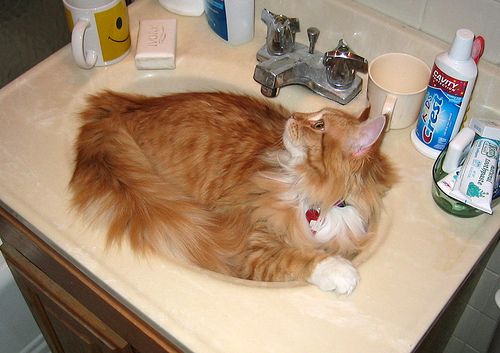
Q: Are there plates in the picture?
A: No, there are no plates.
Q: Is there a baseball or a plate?
A: No, there are no plates or baseballs.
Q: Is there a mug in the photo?
A: Yes, there is a mug.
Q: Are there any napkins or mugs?
A: Yes, there is a mug.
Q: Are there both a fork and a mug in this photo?
A: No, there is a mug but no forks.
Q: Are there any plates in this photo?
A: No, there are no plates.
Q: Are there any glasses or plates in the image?
A: No, there are no plates or glasses.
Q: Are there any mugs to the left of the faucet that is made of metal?
A: Yes, there is a mug to the left of the faucet.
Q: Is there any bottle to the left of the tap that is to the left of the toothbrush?
A: No, there is a mug to the left of the tap.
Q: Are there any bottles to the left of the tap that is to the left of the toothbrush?
A: No, there is a mug to the left of the tap.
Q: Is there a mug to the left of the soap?
A: Yes, there is a mug to the left of the soap.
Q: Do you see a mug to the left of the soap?
A: Yes, there is a mug to the left of the soap.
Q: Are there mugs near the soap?
A: Yes, there is a mug near the soap.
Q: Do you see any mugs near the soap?
A: Yes, there is a mug near the soap.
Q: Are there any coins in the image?
A: No, there are no coins.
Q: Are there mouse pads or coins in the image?
A: No, there are no coins or mouse pads.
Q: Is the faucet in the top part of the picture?
A: Yes, the faucet is in the top of the image.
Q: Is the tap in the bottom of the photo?
A: No, the tap is in the top of the image.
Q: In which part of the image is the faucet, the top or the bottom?
A: The faucet is in the top of the image.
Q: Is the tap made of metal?
A: Yes, the tap is made of metal.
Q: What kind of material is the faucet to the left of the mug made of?
A: The faucet is made of metal.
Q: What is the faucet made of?
A: The faucet is made of metal.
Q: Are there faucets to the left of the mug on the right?
A: Yes, there is a faucet to the left of the mug.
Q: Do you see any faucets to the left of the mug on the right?
A: Yes, there is a faucet to the left of the mug.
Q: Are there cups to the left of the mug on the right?
A: No, there is a faucet to the left of the mug.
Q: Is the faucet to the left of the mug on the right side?
A: Yes, the faucet is to the left of the mug.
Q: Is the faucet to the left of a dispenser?
A: No, the faucet is to the left of the mug.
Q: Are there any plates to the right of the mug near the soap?
A: No, there is a faucet to the right of the mug.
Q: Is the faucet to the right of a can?
A: No, the faucet is to the right of the mug.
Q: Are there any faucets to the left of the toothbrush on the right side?
A: Yes, there is a faucet to the left of the toothbrush.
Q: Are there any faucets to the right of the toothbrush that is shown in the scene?
A: No, the faucet is to the left of the toothbrush.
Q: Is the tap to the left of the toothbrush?
A: Yes, the tap is to the left of the toothbrush.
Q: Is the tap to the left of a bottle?
A: No, the tap is to the left of the toothbrush.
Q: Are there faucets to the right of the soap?
A: Yes, there is a faucet to the right of the soap.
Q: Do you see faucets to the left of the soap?
A: No, the faucet is to the right of the soap.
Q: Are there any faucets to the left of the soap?
A: No, the faucet is to the right of the soap.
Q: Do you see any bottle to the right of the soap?
A: No, there is a faucet to the right of the soap.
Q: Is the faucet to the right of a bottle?
A: No, the faucet is to the right of the soap.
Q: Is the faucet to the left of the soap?
A: No, the faucet is to the right of the soap.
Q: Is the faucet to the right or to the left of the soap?
A: The faucet is to the right of the soap.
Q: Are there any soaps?
A: Yes, there is a soap.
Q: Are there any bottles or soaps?
A: Yes, there is a soap.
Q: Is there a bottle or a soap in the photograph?
A: Yes, there is a soap.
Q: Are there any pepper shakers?
A: No, there are no pepper shakers.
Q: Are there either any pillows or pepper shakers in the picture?
A: No, there are no pepper shakers or pillows.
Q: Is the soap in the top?
A: Yes, the soap is in the top of the image.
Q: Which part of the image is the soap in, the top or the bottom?
A: The soap is in the top of the image.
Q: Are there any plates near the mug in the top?
A: No, there is a soap near the mug.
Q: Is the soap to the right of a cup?
A: No, the soap is to the right of the mug.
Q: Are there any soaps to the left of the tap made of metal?
A: Yes, there is a soap to the left of the faucet.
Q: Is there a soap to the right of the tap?
A: No, the soap is to the left of the tap.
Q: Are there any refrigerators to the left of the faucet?
A: No, there is a soap to the left of the faucet.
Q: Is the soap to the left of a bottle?
A: No, the soap is to the left of a faucet.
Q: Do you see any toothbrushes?
A: Yes, there is a toothbrush.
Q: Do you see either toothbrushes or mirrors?
A: Yes, there is a toothbrush.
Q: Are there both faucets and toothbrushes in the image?
A: Yes, there are both a toothbrush and a faucet.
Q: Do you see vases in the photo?
A: No, there are no vases.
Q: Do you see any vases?
A: No, there are no vases.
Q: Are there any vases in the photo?
A: No, there are no vases.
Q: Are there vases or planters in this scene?
A: No, there are no vases or planters.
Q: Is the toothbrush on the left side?
A: No, the toothbrush is on the right of the image.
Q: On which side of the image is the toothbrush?
A: The toothbrush is on the right of the image.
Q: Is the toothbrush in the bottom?
A: No, the toothbrush is in the top of the image.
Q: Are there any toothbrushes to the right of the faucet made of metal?
A: Yes, there is a toothbrush to the right of the faucet.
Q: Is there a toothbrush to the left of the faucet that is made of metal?
A: No, the toothbrush is to the right of the tap.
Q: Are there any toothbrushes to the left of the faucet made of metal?
A: No, the toothbrush is to the right of the tap.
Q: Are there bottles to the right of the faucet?
A: No, there is a toothbrush to the right of the faucet.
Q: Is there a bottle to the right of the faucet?
A: No, there is a toothbrush to the right of the faucet.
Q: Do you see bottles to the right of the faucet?
A: No, there is a toothbrush to the right of the faucet.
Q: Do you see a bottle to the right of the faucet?
A: No, there is a toothbrush to the right of the faucet.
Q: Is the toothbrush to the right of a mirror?
A: No, the toothbrush is to the right of a faucet.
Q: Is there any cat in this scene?
A: Yes, there is a cat.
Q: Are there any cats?
A: Yes, there is a cat.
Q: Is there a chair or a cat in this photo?
A: Yes, there is a cat.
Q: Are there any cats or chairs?
A: Yes, there is a cat.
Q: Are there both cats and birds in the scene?
A: No, there is a cat but no birds.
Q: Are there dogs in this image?
A: No, there are no dogs.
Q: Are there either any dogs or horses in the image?
A: No, there are no dogs or horses.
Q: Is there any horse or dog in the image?
A: No, there are no dogs or horses.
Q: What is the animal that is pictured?
A: The animal is a cat.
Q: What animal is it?
A: The animal is a cat.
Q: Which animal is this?
A: This is a cat.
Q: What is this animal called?
A: This is a cat.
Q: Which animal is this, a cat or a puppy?
A: This is a cat.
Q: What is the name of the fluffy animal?
A: The animal is a cat.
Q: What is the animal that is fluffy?
A: The animal is a cat.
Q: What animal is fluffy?
A: The animal is a cat.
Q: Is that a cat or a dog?
A: That is a cat.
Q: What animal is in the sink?
A: The cat is in the sink.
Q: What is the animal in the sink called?
A: The animal is a cat.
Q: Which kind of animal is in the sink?
A: The animal is a cat.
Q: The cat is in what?
A: The cat is in the sink.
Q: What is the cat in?
A: The cat is in the sink.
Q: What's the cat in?
A: The cat is in the sink.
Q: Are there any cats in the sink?
A: Yes, there is a cat in the sink.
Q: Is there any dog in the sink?
A: No, there is a cat in the sink.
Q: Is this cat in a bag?
A: No, the cat is in the sink.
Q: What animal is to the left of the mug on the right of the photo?
A: The animal is a cat.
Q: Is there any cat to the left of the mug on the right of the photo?
A: Yes, there is a cat to the left of the mug.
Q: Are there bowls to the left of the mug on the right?
A: No, there is a cat to the left of the mug.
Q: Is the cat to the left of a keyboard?
A: No, the cat is to the left of a mug.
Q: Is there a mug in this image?
A: Yes, there is a mug.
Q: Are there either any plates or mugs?
A: Yes, there is a mug.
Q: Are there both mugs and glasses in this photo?
A: No, there is a mug but no glasses.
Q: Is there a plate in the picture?
A: No, there are no plates.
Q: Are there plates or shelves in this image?
A: No, there are no plates or shelves.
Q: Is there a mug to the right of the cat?
A: Yes, there is a mug to the right of the cat.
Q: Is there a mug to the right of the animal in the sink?
A: Yes, there is a mug to the right of the cat.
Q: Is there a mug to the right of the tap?
A: Yes, there is a mug to the right of the tap.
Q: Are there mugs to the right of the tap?
A: Yes, there is a mug to the right of the tap.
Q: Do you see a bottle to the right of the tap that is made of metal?
A: No, there is a mug to the right of the faucet.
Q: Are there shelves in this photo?
A: No, there are no shelves.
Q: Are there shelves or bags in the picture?
A: No, there are no shelves or bags.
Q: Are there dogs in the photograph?
A: No, there are no dogs.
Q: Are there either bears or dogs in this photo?
A: No, there are no dogs or bears.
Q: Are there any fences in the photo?
A: No, there are no fences.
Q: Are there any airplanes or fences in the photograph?
A: No, there are no fences or airplanes.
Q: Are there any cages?
A: No, there are no cages.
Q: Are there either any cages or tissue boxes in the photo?
A: No, there are no cages or tissue boxes.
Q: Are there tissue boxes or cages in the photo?
A: No, there are no cages or tissue boxes.